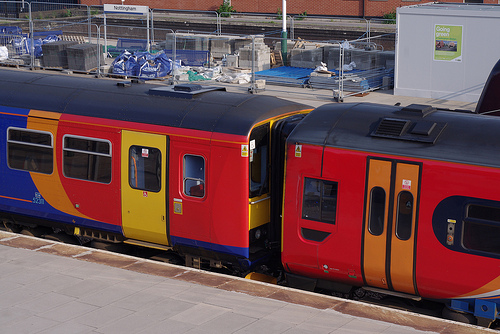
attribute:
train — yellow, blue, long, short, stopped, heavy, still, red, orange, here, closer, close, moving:
[19, 87, 483, 294]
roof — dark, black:
[218, 90, 269, 134]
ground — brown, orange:
[37, 244, 237, 333]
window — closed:
[126, 142, 164, 201]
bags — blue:
[99, 25, 190, 81]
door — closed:
[121, 121, 177, 249]